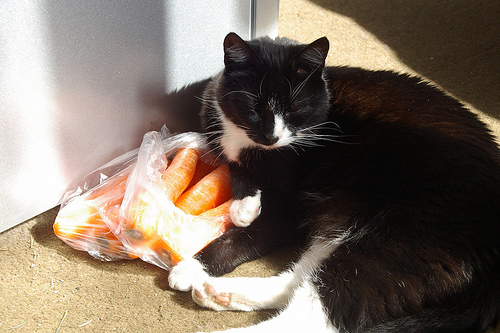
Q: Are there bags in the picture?
A: Yes, there is a bag.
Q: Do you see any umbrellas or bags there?
A: Yes, there is a bag.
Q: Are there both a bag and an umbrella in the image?
A: No, there is a bag but no umbrellas.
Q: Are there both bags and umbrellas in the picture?
A: No, there is a bag but no umbrellas.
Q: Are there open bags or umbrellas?
A: Yes, there is an open bag.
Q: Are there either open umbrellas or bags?
A: Yes, there is an open bag.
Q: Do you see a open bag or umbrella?
A: Yes, there is an open bag.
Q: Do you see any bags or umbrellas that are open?
A: Yes, the bag is open.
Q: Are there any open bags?
A: Yes, there is an open bag.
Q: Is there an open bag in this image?
A: Yes, there is an open bag.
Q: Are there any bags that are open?
A: Yes, there is a bag that is open.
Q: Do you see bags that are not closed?
A: Yes, there is a open bag.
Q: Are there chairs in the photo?
A: No, there are no chairs.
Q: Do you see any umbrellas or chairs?
A: No, there are no chairs or umbrellas.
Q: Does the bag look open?
A: Yes, the bag is open.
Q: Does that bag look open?
A: Yes, the bag is open.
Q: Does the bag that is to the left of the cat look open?
A: Yes, the bag is open.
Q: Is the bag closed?
A: No, the bag is open.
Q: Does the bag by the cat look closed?
A: No, the bag is open.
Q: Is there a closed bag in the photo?
A: No, there is a bag but it is open.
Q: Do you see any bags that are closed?
A: No, there is a bag but it is open.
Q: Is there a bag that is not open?
A: No, there is a bag but it is open.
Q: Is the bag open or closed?
A: The bag is open.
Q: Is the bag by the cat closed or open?
A: The bag is open.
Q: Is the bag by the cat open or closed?
A: The bag is open.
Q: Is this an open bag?
A: Yes, this is an open bag.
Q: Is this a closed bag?
A: No, this is an open bag.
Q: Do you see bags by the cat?
A: Yes, there is a bag by the cat.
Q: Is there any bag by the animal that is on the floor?
A: Yes, there is a bag by the cat.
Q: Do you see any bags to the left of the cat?
A: Yes, there is a bag to the left of the cat.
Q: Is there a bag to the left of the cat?
A: Yes, there is a bag to the left of the cat.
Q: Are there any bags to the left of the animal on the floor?
A: Yes, there is a bag to the left of the cat.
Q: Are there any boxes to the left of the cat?
A: No, there is a bag to the left of the cat.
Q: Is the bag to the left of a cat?
A: Yes, the bag is to the left of a cat.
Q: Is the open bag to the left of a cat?
A: Yes, the bag is to the left of a cat.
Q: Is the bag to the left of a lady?
A: No, the bag is to the left of a cat.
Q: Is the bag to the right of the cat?
A: No, the bag is to the left of the cat.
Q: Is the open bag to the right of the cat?
A: No, the bag is to the left of the cat.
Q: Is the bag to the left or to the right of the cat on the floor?
A: The bag is to the left of the cat.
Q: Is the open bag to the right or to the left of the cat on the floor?
A: The bag is to the left of the cat.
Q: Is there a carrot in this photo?
A: Yes, there is a carrot.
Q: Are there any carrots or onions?
A: Yes, there is a carrot.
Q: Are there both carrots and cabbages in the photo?
A: No, there is a carrot but no cabbages.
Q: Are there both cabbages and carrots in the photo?
A: No, there is a carrot but no cabbages.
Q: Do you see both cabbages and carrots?
A: No, there is a carrot but no cabbages.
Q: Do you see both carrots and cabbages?
A: No, there is a carrot but no cabbages.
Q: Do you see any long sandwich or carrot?
A: Yes, there is a long carrot.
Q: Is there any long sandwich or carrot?
A: Yes, there is a long carrot.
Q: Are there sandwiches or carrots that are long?
A: Yes, the carrot is long.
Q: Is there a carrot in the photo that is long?
A: Yes, there is a long carrot.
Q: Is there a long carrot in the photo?
A: Yes, there is a long carrot.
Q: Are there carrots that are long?
A: Yes, there is a carrot that is long.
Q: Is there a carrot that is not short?
A: Yes, there is a long carrot.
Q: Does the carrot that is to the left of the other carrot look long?
A: Yes, the carrot is long.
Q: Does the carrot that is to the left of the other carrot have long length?
A: Yes, the carrot is long.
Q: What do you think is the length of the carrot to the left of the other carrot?
A: The carrot is long.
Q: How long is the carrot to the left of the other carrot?
A: The carrot is long.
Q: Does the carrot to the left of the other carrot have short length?
A: No, the carrot is long.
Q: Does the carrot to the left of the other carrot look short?
A: No, the carrot is long.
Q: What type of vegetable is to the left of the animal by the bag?
A: The vegetable is a carrot.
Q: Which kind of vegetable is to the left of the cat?
A: The vegetable is a carrot.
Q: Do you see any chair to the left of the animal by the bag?
A: No, there is a carrot to the left of the cat.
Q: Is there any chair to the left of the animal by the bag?
A: No, there is a carrot to the left of the cat.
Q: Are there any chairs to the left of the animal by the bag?
A: No, there is a carrot to the left of the cat.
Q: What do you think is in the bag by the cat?
A: The carrot is in the bag.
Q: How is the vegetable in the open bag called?
A: The vegetable is a carrot.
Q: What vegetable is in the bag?
A: The vegetable is a carrot.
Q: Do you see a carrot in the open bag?
A: Yes, there is a carrot in the bag.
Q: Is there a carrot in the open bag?
A: Yes, there is a carrot in the bag.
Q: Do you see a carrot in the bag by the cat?
A: Yes, there is a carrot in the bag.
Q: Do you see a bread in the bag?
A: No, there is a carrot in the bag.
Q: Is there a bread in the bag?
A: No, there is a carrot in the bag.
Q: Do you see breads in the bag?
A: No, there is a carrot in the bag.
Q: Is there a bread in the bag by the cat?
A: No, there is a carrot in the bag.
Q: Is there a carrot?
A: Yes, there is a carrot.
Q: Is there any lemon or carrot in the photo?
A: Yes, there is a carrot.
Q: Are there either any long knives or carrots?
A: Yes, there is a long carrot.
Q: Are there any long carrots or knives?
A: Yes, there is a long carrot.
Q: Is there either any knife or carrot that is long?
A: Yes, the carrot is long.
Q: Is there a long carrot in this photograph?
A: Yes, there is a long carrot.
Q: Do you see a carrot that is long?
A: Yes, there is a carrot that is long.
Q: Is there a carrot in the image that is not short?
A: Yes, there is a long carrot.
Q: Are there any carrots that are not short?
A: Yes, there is a long carrot.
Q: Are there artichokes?
A: No, there are no artichokes.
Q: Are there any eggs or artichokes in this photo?
A: No, there are no artichokes or eggs.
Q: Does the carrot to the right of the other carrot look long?
A: Yes, the carrot is long.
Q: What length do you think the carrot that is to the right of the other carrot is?
A: The carrot is long.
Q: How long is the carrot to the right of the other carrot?
A: The carrot is long.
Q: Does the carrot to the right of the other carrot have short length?
A: No, the carrot is long.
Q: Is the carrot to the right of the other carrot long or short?
A: The carrot is long.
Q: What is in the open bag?
A: The carrot is in the bag.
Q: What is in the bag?
A: The carrot is in the bag.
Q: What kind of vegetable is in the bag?
A: The vegetable is a carrot.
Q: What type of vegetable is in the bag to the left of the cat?
A: The vegetable is a carrot.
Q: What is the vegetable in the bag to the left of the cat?
A: The vegetable is a carrot.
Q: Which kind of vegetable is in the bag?
A: The vegetable is a carrot.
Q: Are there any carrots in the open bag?
A: Yes, there is a carrot in the bag.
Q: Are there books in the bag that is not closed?
A: No, there is a carrot in the bag.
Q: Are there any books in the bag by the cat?
A: No, there is a carrot in the bag.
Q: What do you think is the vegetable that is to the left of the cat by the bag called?
A: The vegetable is a carrot.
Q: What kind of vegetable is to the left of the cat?
A: The vegetable is a carrot.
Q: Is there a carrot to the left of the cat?
A: Yes, there is a carrot to the left of the cat.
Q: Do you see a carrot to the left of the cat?
A: Yes, there is a carrot to the left of the cat.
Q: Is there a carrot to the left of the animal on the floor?
A: Yes, there is a carrot to the left of the cat.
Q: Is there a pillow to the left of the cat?
A: No, there is a carrot to the left of the cat.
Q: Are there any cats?
A: Yes, there is a cat.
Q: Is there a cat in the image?
A: Yes, there is a cat.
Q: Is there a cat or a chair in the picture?
A: Yes, there is a cat.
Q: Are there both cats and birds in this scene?
A: No, there is a cat but no birds.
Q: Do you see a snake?
A: No, there are no snakes.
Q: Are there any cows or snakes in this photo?
A: No, there are no snakes or cows.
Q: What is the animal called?
A: The animal is a cat.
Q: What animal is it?
A: The animal is a cat.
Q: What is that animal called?
A: This is a cat.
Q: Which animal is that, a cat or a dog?
A: This is a cat.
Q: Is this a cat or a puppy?
A: This is a cat.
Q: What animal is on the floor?
A: The cat is on the floor.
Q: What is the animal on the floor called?
A: The animal is a cat.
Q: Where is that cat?
A: The cat is on the floor.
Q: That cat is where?
A: The cat is on the floor.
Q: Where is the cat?
A: The cat is on the floor.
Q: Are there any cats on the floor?
A: Yes, there is a cat on the floor.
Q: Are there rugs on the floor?
A: No, there is a cat on the floor.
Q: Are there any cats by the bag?
A: Yes, there is a cat by the bag.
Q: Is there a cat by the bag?
A: Yes, there is a cat by the bag.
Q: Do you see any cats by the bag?
A: Yes, there is a cat by the bag.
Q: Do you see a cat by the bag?
A: Yes, there is a cat by the bag.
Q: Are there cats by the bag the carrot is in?
A: Yes, there is a cat by the bag.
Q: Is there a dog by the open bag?
A: No, there is a cat by the bag.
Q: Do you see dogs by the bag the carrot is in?
A: No, there is a cat by the bag.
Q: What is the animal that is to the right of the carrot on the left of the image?
A: The animal is a cat.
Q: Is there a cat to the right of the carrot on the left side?
A: Yes, there is a cat to the right of the carrot.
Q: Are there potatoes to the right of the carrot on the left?
A: No, there is a cat to the right of the carrot.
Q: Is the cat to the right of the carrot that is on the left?
A: Yes, the cat is to the right of the carrot.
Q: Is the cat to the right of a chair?
A: No, the cat is to the right of the carrot.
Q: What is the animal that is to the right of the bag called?
A: The animal is a cat.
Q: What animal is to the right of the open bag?
A: The animal is a cat.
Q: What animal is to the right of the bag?
A: The animal is a cat.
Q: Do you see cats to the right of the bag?
A: Yes, there is a cat to the right of the bag.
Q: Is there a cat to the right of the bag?
A: Yes, there is a cat to the right of the bag.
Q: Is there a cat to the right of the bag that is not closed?
A: Yes, there is a cat to the right of the bag.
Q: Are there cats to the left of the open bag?
A: No, the cat is to the right of the bag.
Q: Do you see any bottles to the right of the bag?
A: No, there is a cat to the right of the bag.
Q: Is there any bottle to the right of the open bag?
A: No, there is a cat to the right of the bag.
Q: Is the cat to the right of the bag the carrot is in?
A: Yes, the cat is to the right of the bag.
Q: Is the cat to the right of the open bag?
A: Yes, the cat is to the right of the bag.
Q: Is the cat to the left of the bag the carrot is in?
A: No, the cat is to the right of the bag.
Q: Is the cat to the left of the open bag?
A: No, the cat is to the right of the bag.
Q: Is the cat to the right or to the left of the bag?
A: The cat is to the right of the bag.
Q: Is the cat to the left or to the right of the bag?
A: The cat is to the right of the bag.